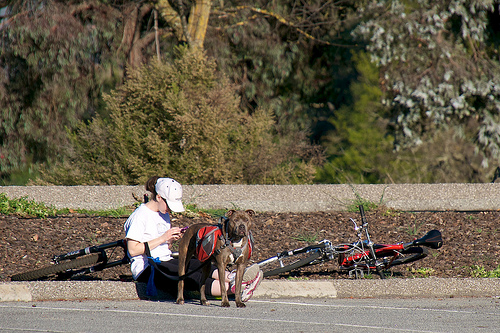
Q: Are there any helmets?
A: No, there are no helmets.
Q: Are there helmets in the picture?
A: No, there are no helmets.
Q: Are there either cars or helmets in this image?
A: No, there are no helmets or cars.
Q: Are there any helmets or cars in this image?
A: No, there are no helmets or cars.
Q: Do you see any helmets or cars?
A: No, there are no helmets or cars.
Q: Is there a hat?
A: Yes, there is a hat.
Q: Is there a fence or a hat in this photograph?
A: Yes, there is a hat.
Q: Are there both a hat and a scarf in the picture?
A: No, there is a hat but no scarves.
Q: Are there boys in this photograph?
A: No, there are no boys.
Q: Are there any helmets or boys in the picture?
A: No, there are no boys or helmets.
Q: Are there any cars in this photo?
A: No, there are no cars.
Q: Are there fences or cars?
A: No, there are no cars or fences.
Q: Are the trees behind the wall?
A: Yes, the trees are behind the wall.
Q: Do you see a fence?
A: No, there are no fences.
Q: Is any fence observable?
A: No, there are no fences.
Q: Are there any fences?
A: No, there are no fences.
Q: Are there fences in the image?
A: No, there are no fences.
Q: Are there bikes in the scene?
A: Yes, there is a bike.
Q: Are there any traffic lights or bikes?
A: Yes, there is a bike.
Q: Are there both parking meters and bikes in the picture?
A: No, there is a bike but no parking meters.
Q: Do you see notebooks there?
A: No, there are no notebooks.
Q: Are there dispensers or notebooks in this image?
A: No, there are no notebooks or dispensers.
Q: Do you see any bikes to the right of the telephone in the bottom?
A: Yes, there is a bike to the right of the telephone.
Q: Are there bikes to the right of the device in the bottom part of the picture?
A: Yes, there is a bike to the right of the telephone.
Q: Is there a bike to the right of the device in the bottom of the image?
A: Yes, there is a bike to the right of the telephone.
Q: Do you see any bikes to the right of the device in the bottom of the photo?
A: Yes, there is a bike to the right of the telephone.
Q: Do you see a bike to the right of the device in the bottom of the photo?
A: Yes, there is a bike to the right of the telephone.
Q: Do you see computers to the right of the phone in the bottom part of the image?
A: No, there is a bike to the right of the telephone.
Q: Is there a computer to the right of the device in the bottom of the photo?
A: No, there is a bike to the right of the telephone.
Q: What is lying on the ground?
A: The bike is lying on the ground.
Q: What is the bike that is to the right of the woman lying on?
A: The bike is lying on the ground.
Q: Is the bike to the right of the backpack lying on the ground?
A: Yes, the bike is lying on the ground.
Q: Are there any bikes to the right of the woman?
A: Yes, there is a bike to the right of the woman.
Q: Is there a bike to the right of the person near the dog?
A: Yes, there is a bike to the right of the woman.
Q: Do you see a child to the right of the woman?
A: No, there is a bike to the right of the woman.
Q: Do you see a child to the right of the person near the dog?
A: No, there is a bike to the right of the woman.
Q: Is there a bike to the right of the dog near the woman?
A: Yes, there is a bike to the right of the dog.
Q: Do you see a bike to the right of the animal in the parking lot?
A: Yes, there is a bike to the right of the dog.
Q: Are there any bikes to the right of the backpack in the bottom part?
A: Yes, there is a bike to the right of the backpack.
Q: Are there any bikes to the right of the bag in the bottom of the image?
A: Yes, there is a bike to the right of the backpack.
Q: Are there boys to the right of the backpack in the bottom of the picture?
A: No, there is a bike to the right of the backpack.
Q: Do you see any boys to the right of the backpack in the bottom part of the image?
A: No, there is a bike to the right of the backpack.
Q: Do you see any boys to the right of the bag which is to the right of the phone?
A: No, there is a bike to the right of the backpack.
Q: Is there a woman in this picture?
A: Yes, there is a woman.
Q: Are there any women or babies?
A: Yes, there is a woman.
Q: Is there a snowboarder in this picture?
A: No, there are no snowboarders.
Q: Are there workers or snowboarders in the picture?
A: No, there are no snowboarders or workers.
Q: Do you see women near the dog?
A: Yes, there is a woman near the dog.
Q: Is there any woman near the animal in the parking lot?
A: Yes, there is a woman near the dog.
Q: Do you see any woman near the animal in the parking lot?
A: Yes, there is a woman near the dog.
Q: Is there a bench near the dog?
A: No, there is a woman near the dog.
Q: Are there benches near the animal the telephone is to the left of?
A: No, there is a woman near the dog.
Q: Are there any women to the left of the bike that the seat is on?
A: Yes, there is a woman to the left of the bike.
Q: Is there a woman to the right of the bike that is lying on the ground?
A: No, the woman is to the left of the bike.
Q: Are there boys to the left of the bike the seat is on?
A: No, there is a woman to the left of the bike.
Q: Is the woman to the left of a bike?
A: Yes, the woman is to the left of a bike.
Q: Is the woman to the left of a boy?
A: No, the woman is to the left of a bike.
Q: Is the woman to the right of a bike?
A: No, the woman is to the left of a bike.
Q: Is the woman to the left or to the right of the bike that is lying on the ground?
A: The woman is to the left of the bike.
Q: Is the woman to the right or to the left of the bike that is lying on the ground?
A: The woman is to the left of the bike.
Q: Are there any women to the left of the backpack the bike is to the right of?
A: Yes, there is a woman to the left of the backpack.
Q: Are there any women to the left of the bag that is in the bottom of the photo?
A: Yes, there is a woman to the left of the backpack.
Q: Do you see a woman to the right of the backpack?
A: No, the woman is to the left of the backpack.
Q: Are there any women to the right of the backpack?
A: No, the woman is to the left of the backpack.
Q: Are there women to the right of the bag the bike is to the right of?
A: No, the woman is to the left of the backpack.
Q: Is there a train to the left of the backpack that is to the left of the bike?
A: No, there is a woman to the left of the backpack.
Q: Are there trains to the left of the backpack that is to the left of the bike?
A: No, there is a woman to the left of the backpack.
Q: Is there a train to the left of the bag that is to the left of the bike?
A: No, there is a woman to the left of the backpack.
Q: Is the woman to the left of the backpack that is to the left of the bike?
A: Yes, the woman is to the left of the backpack.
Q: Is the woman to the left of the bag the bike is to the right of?
A: Yes, the woman is to the left of the backpack.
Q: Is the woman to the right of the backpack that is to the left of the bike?
A: No, the woman is to the left of the backpack.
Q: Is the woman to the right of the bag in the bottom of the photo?
A: No, the woman is to the left of the backpack.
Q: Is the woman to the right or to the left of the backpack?
A: The woman is to the left of the backpack.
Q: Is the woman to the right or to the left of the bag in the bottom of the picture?
A: The woman is to the left of the backpack.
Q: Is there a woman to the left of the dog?
A: Yes, there is a woman to the left of the dog.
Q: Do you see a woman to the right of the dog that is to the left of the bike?
A: No, the woman is to the left of the dog.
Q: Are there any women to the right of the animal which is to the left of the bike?
A: No, the woman is to the left of the dog.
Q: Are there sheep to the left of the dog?
A: No, there is a woman to the left of the dog.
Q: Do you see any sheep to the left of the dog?
A: No, there is a woman to the left of the dog.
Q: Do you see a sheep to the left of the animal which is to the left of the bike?
A: No, there is a woman to the left of the dog.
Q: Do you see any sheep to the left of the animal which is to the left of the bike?
A: No, there is a woman to the left of the dog.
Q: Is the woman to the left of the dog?
A: Yes, the woman is to the left of the dog.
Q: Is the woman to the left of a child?
A: No, the woman is to the left of the dog.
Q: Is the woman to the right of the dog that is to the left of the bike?
A: No, the woman is to the left of the dog.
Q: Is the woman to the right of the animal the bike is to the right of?
A: No, the woman is to the left of the dog.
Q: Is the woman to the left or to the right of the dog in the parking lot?
A: The woman is to the left of the dog.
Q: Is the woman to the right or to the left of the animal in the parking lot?
A: The woman is to the left of the dog.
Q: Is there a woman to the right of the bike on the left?
A: Yes, there is a woman to the right of the bike.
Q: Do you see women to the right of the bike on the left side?
A: Yes, there is a woman to the right of the bike.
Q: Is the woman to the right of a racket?
A: No, the woman is to the right of the bike.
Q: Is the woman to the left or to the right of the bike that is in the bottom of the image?
A: The woman is to the right of the bike.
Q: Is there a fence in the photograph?
A: No, there are no fences.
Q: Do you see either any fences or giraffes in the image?
A: No, there are no fences or giraffes.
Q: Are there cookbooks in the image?
A: No, there are no cookbooks.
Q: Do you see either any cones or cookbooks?
A: No, there are no cookbooks or cones.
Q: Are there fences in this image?
A: No, there are no fences.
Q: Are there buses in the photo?
A: No, there are no buses.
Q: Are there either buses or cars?
A: No, there are no buses or cars.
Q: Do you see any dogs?
A: Yes, there is a dog.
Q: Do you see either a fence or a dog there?
A: Yes, there is a dog.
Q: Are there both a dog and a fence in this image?
A: No, there is a dog but no fences.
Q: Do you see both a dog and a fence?
A: No, there is a dog but no fences.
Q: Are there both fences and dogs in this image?
A: No, there is a dog but no fences.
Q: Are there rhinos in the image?
A: No, there are no rhinos.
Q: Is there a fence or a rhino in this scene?
A: No, there are no rhinos or fences.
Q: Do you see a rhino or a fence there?
A: No, there are no rhinos or fences.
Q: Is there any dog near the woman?
A: Yes, there is a dog near the woman.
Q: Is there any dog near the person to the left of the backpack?
A: Yes, there is a dog near the woman.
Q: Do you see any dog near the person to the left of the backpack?
A: Yes, there is a dog near the woman.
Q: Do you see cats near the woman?
A: No, there is a dog near the woman.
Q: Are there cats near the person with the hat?
A: No, there is a dog near the woman.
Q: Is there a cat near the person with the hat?
A: No, there is a dog near the woman.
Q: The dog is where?
A: The dog is in the parking lot.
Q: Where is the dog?
A: The dog is in the parking lot.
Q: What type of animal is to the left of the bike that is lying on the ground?
A: The animal is a dog.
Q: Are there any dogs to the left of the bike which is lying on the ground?
A: Yes, there is a dog to the left of the bike.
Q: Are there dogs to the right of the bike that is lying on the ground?
A: No, the dog is to the left of the bike.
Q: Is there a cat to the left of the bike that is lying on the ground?
A: No, there is a dog to the left of the bike.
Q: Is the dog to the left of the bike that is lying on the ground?
A: Yes, the dog is to the left of the bike.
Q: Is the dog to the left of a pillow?
A: No, the dog is to the left of the bike.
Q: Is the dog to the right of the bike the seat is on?
A: No, the dog is to the left of the bike.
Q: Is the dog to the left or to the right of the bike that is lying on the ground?
A: The dog is to the left of the bike.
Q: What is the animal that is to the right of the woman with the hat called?
A: The animal is a dog.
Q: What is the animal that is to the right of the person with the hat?
A: The animal is a dog.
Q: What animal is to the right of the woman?
A: The animal is a dog.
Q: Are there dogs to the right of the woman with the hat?
A: Yes, there is a dog to the right of the woman.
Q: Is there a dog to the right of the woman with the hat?
A: Yes, there is a dog to the right of the woman.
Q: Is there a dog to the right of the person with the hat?
A: Yes, there is a dog to the right of the woman.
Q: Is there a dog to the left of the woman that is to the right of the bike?
A: No, the dog is to the right of the woman.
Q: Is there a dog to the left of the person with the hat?
A: No, the dog is to the right of the woman.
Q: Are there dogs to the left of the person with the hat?
A: No, the dog is to the right of the woman.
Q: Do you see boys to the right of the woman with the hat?
A: No, there is a dog to the right of the woman.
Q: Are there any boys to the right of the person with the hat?
A: No, there is a dog to the right of the woman.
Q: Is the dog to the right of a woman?
A: Yes, the dog is to the right of a woman.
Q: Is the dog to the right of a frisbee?
A: No, the dog is to the right of a woman.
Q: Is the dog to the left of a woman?
A: No, the dog is to the right of a woman.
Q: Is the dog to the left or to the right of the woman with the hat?
A: The dog is to the right of the woman.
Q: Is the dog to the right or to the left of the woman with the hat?
A: The dog is to the right of the woman.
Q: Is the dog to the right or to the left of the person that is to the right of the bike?
A: The dog is to the right of the woman.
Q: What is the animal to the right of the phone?
A: The animal is a dog.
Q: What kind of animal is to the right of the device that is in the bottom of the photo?
A: The animal is a dog.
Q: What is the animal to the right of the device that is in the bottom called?
A: The animal is a dog.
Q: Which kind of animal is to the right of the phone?
A: The animal is a dog.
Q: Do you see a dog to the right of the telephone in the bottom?
A: Yes, there is a dog to the right of the phone.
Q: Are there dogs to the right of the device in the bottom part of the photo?
A: Yes, there is a dog to the right of the phone.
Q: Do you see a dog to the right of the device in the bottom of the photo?
A: Yes, there is a dog to the right of the phone.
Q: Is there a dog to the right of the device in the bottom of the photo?
A: Yes, there is a dog to the right of the phone.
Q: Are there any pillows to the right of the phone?
A: No, there is a dog to the right of the phone.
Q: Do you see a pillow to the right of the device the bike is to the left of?
A: No, there is a dog to the right of the phone.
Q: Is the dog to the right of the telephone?
A: Yes, the dog is to the right of the telephone.